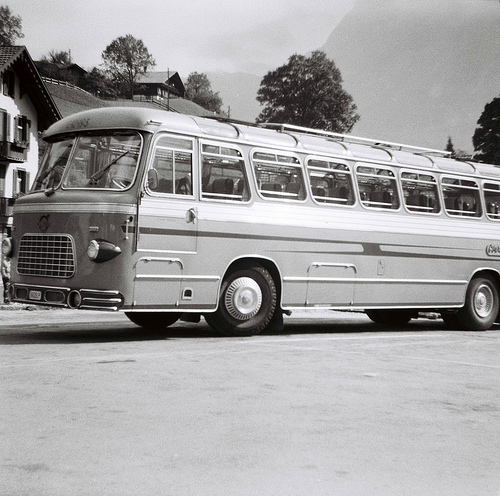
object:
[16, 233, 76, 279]
grill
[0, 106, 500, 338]
bus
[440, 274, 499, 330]
wheel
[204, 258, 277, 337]
wheel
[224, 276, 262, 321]
hub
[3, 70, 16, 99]
window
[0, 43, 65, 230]
house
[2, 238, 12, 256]
headlight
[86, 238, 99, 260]
headlight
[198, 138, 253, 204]
window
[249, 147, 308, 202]
window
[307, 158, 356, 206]
window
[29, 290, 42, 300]
plate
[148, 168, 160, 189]
mirror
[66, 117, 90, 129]
number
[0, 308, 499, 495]
road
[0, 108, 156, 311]
front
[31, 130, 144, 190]
windshield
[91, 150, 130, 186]
wiper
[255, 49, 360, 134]
tree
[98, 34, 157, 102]
tree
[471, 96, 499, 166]
tree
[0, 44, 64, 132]
roof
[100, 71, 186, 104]
house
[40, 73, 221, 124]
hill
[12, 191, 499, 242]
stripe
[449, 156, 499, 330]
rear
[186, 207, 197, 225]
handle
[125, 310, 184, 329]
tire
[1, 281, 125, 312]
bumper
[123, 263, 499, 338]
wheels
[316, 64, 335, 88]
leaves